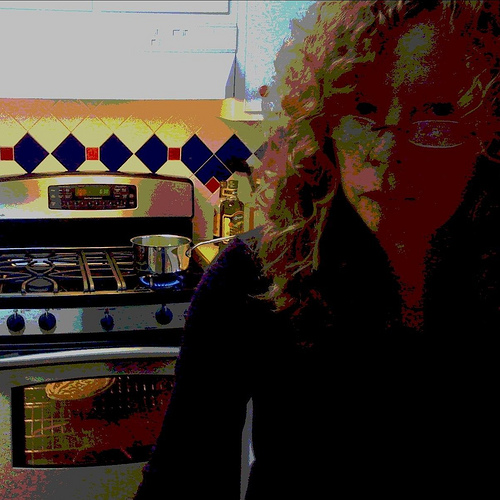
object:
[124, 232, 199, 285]
pan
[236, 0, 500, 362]
blonde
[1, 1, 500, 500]
kitchen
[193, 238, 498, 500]
top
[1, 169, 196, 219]
control panel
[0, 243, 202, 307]
stove top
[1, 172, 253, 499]
oven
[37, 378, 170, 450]
food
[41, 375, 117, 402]
pizza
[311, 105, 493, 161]
glasses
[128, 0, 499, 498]
woman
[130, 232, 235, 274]
pot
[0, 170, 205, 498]
stove